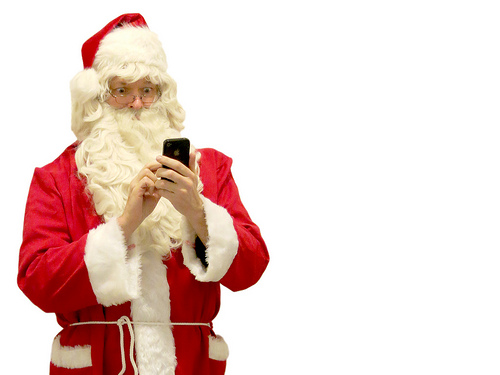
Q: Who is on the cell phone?
A: Santa Claus.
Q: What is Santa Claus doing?
A: Looking at a cell phone.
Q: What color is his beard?
A: White.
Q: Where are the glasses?
A: On his face.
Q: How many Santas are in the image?
A: One.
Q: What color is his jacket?
A: White and Red.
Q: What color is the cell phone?
A: Black.